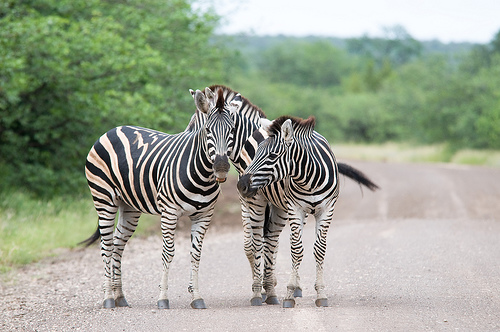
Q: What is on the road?
A: Zebras.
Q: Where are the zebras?
A: On the road.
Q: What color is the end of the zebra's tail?
A: Black.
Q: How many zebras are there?
A: Three.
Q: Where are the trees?
A: Behind the zebras.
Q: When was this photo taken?
A: During the day.